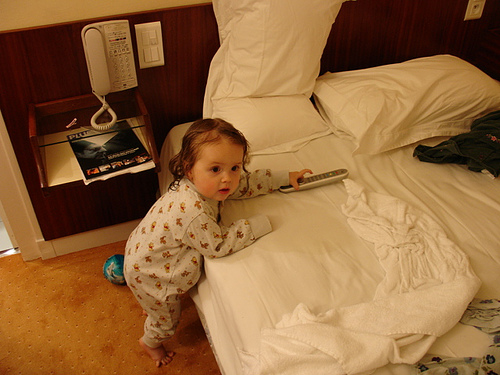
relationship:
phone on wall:
[81, 19, 140, 132] [1, 1, 499, 260]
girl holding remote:
[122, 118, 315, 366] [279, 168, 350, 195]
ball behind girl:
[103, 254, 127, 285] [122, 118, 315, 366]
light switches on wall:
[133, 22, 165, 70] [1, 1, 499, 260]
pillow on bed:
[202, 3, 345, 157] [155, 121, 497, 373]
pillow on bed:
[310, 54, 499, 155] [155, 121, 497, 373]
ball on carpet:
[103, 254, 127, 285] [0, 238, 224, 374]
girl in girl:
[122, 118, 315, 366] [122, 118, 315, 366]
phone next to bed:
[81, 19, 140, 132] [155, 121, 497, 373]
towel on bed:
[260, 179, 483, 374] [155, 121, 497, 373]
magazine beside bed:
[68, 118, 152, 179] [155, 121, 497, 373]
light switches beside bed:
[133, 22, 165, 70] [155, 121, 497, 373]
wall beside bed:
[1, 1, 499, 260] [155, 121, 497, 373]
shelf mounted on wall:
[28, 89, 161, 195] [1, 1, 499, 260]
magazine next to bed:
[68, 118, 152, 179] [155, 121, 497, 373]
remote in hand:
[279, 168, 350, 195] [288, 169, 314, 190]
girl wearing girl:
[122, 118, 315, 366] [122, 118, 315, 366]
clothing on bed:
[413, 108, 500, 177] [155, 121, 497, 373]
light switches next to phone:
[133, 22, 165, 70] [81, 19, 140, 132]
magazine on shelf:
[68, 118, 152, 179] [28, 89, 161, 195]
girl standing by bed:
[122, 118, 315, 366] [155, 121, 497, 373]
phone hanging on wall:
[81, 19, 140, 132] [1, 1, 499, 260]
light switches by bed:
[133, 22, 165, 70] [155, 121, 497, 373]